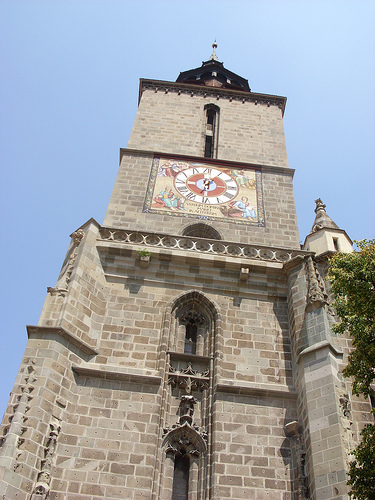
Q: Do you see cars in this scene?
A: No, there are no cars.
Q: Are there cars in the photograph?
A: No, there are no cars.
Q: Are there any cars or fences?
A: No, there are no cars or fences.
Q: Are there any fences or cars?
A: No, there are no cars or fences.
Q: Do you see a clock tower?
A: Yes, there is a clock tower.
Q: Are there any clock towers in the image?
A: Yes, there is a clock tower.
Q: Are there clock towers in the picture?
A: Yes, there is a clock tower.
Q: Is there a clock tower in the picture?
A: Yes, there is a clock tower.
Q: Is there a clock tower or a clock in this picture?
A: Yes, there is a clock tower.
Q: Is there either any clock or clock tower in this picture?
A: Yes, there is a clock tower.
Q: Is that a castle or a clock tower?
A: That is a clock tower.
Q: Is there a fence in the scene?
A: No, there are no fences.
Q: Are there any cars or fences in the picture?
A: No, there are no fences or cars.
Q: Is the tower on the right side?
A: Yes, the tower is on the right of the image.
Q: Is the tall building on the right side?
A: Yes, the tower is on the right of the image.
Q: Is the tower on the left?
A: No, the tower is on the right of the image.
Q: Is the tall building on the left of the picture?
A: No, the tower is on the right of the image.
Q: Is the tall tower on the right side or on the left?
A: The tower is on the right of the image.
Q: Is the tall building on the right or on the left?
A: The tower is on the right of the image.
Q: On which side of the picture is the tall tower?
A: The tower is on the right of the image.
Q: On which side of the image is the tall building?
A: The tower is on the right of the image.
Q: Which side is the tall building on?
A: The tower is on the right of the image.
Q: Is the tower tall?
A: Yes, the tower is tall.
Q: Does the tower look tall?
A: Yes, the tower is tall.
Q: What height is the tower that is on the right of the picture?
A: The tower is tall.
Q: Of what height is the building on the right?
A: The tower is tall.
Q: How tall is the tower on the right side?
A: The tower is tall.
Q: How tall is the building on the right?
A: The tower is tall.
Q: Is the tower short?
A: No, the tower is tall.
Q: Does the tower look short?
A: No, the tower is tall.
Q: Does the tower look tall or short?
A: The tower is tall.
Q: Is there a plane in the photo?
A: No, there are no airplanes.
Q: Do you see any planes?
A: No, there are no planes.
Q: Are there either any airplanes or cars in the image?
A: No, there are no airplanes or cars.